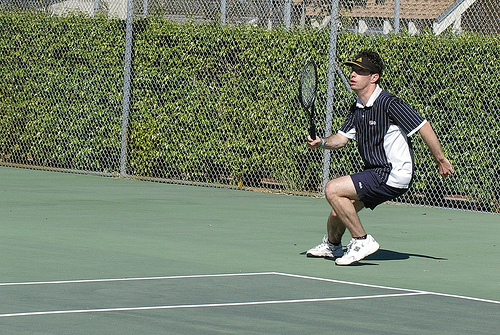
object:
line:
[0, 272, 279, 285]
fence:
[0, 0, 499, 216]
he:
[298, 49, 454, 266]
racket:
[298, 62, 318, 141]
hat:
[344, 51, 386, 74]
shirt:
[335, 82, 426, 189]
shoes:
[335, 235, 382, 267]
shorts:
[349, 170, 403, 208]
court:
[0, 163, 499, 333]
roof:
[303, 0, 459, 20]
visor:
[342, 57, 379, 74]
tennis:
[0, 0, 500, 335]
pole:
[119, 1, 133, 176]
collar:
[355, 81, 384, 108]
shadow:
[302, 242, 446, 265]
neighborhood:
[30, 0, 500, 33]